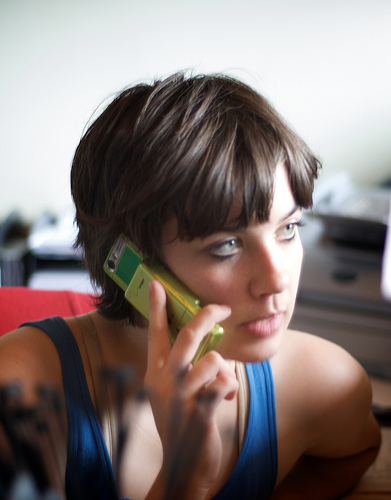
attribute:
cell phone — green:
[96, 238, 238, 356]